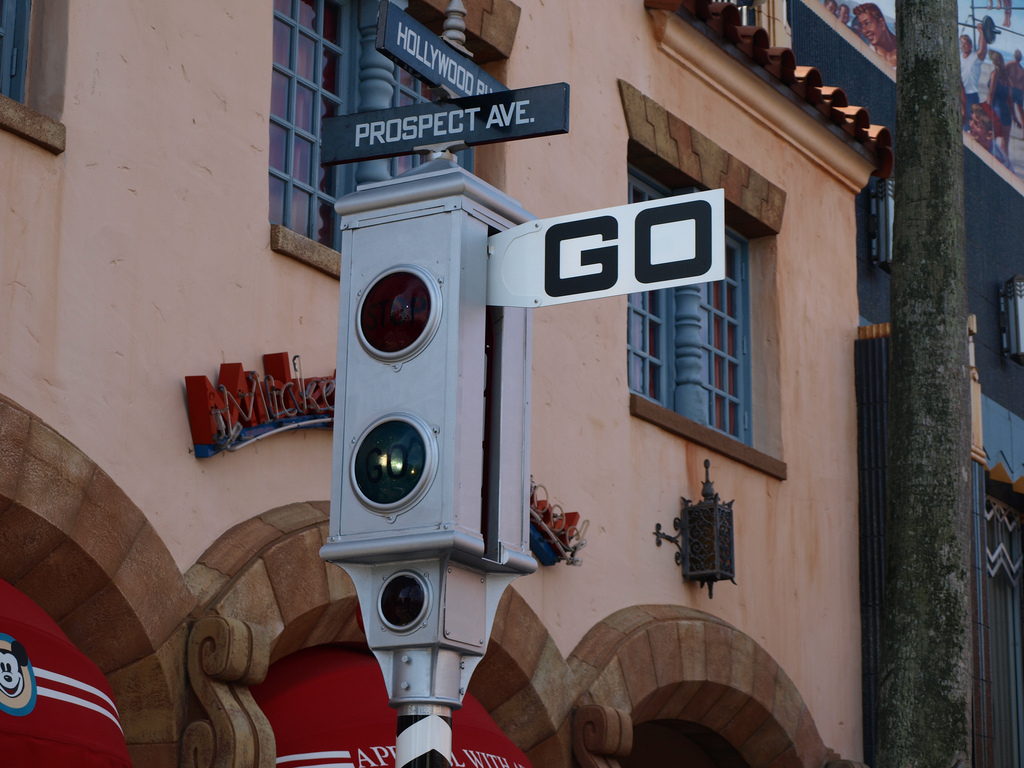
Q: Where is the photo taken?
A: Prospect ave.